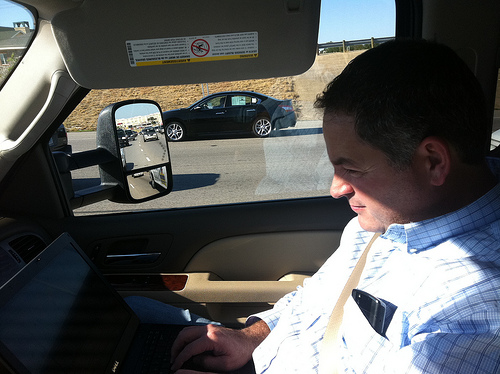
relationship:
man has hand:
[120, 39, 498, 369] [164, 316, 253, 371]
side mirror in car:
[112, 102, 174, 202] [0, 1, 483, 370]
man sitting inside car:
[120, 34, 485, 369] [0, 1, 483, 370]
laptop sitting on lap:
[0, 230, 233, 371] [122, 291, 246, 371]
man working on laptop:
[120, 34, 485, 369] [0, 230, 233, 371]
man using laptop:
[120, 34, 485, 369] [0, 230, 233, 371]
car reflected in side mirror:
[140, 124, 160, 144] [90, 96, 174, 206]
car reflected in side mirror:
[152, 125, 161, 134] [90, 96, 174, 206]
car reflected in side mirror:
[116, 127, 129, 148] [90, 96, 174, 206]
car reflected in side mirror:
[122, 129, 134, 141] [90, 96, 174, 206]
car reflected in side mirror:
[147, 162, 168, 190] [90, 96, 174, 206]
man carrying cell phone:
[120, 34, 485, 369] [349, 286, 388, 334]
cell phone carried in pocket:
[349, 286, 388, 334] [329, 297, 386, 373]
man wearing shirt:
[120, 39, 498, 369] [246, 198, 488, 372]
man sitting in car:
[120, 39, 498, 369] [0, 1, 483, 370]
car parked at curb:
[156, 90, 298, 144] [70, 127, 321, 139]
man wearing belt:
[120, 39, 498, 369] [316, 224, 386, 372]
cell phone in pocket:
[349, 287, 391, 336] [332, 300, 383, 370]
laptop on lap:
[9, 234, 193, 371] [134, 295, 245, 344]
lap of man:
[134, 295, 245, 344] [120, 34, 485, 369]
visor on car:
[49, 10, 322, 83] [9, 5, 477, 324]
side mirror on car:
[97, 100, 176, 202] [0, 1, 483, 370]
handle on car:
[106, 248, 173, 266] [0, 1, 483, 370]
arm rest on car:
[166, 265, 296, 305] [9, 5, 477, 324]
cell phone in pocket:
[354, 290, 388, 334] [332, 300, 383, 370]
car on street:
[155, 90, 290, 140] [78, 129, 334, 207]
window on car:
[201, 94, 227, 114] [156, 90, 298, 144]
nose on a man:
[328, 172, 355, 202] [120, 39, 498, 369]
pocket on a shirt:
[329, 297, 382, 373] [246, 198, 488, 372]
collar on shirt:
[381, 197, 498, 267] [234, 204, 498, 371]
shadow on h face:
[318, 114, 440, 220] [315, 110, 440, 240]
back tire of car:
[249, 118, 274, 138] [163, 85, 293, 142]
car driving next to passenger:
[156, 90, 298, 144] [98, 32, 484, 371]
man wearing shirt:
[120, 34, 485, 369] [242, 180, 483, 372]